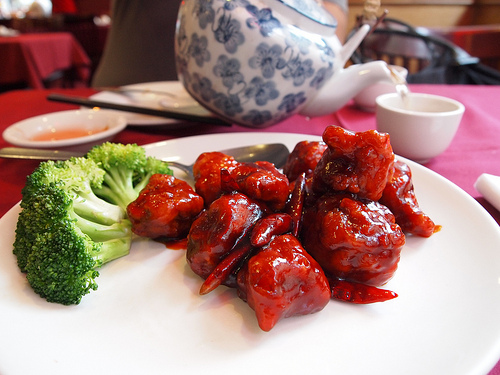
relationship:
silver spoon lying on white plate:
[3, 141, 287, 167] [0, 132, 500, 372]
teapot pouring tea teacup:
[164, 0, 446, 132] [369, 79, 464, 160]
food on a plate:
[136, 110, 425, 329] [12, 125, 498, 374]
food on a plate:
[10, 124, 444, 332] [12, 125, 498, 374]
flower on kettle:
[214, 6, 244, 63] [174, 0, 402, 129]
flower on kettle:
[254, 34, 282, 81] [174, 0, 402, 129]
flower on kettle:
[283, 47, 311, 89] [174, 0, 402, 129]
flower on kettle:
[180, 28, 212, 75] [174, 0, 402, 129]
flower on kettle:
[211, 45, 254, 97] [174, 0, 402, 129]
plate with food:
[12, 125, 498, 374] [10, 124, 444, 332]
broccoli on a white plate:
[13, 140, 175, 305] [0, 132, 500, 372]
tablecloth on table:
[410, 74, 495, 168] [92, 68, 496, 372]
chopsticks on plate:
[70, 75, 235, 155] [350, 293, 452, 345]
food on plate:
[10, 124, 444, 332] [90, 138, 499, 369]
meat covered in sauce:
[235, 170, 393, 226] [182, 170, 410, 283]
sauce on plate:
[182, 170, 410, 283] [12, 125, 498, 374]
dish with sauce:
[1, 105, 127, 155] [26, 127, 110, 141]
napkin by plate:
[471, 170, 489, 208] [3, 135, 474, 374]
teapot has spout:
[172, 1, 405, 129] [302, 59, 397, 124]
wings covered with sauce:
[120, 122, 465, 331] [125, 122, 439, 331]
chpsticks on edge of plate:
[42, 90, 231, 127] [95, 81, 213, 134]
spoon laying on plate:
[2, 143, 295, 173] [12, 125, 498, 374]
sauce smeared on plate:
[166, 233, 188, 251] [12, 125, 498, 374]